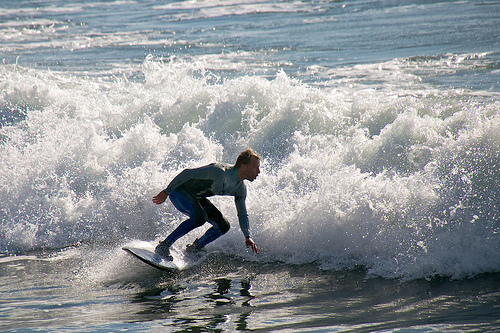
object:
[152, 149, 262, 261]
man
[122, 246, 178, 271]
board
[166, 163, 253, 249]
suit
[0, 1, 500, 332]
water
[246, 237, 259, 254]
hand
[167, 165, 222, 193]
arm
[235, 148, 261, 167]
hair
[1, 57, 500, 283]
wave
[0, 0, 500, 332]
ocean